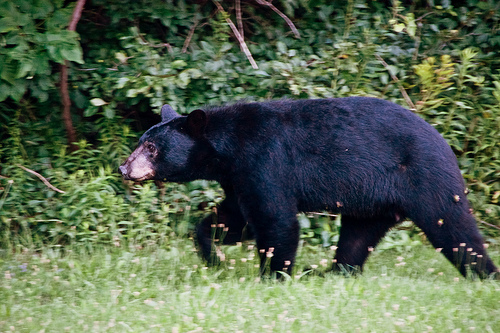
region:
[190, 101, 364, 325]
A black bear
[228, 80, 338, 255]
A black bear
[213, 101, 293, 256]
A black bear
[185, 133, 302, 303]
A black bear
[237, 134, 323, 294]
A black bear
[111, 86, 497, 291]
bear walking in the grass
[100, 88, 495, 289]
fuzzy black bear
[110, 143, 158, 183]
lighter colored snout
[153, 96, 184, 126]
rounded top, black ear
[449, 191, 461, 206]
light piece of nature sticking to the bear's fur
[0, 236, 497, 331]
patch of light green grass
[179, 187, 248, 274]
front leg is bent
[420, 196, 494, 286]
back leg is extended back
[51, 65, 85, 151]
skinny brown tree trunk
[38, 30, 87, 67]
large green leaf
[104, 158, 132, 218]
Bear has black nose.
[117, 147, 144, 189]
Bear has brown face.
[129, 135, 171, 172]
Bear has brown eyes.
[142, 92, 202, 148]
Bear has black ears.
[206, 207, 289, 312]
Bear has black front legs.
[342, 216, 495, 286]
Bear has black back paws.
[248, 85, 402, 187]
Bear has black back fur.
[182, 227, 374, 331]
Bear is walking through grass.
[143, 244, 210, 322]
Grass is green near bear.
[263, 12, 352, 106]
Leaves are green on tree.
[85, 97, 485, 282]
the bear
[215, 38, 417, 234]
the bear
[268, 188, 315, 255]
the bear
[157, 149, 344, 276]
the bear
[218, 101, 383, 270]
the bear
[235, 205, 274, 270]
the bear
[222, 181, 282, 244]
the bear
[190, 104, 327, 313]
the bear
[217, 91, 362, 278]
A bear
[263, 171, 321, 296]
A bear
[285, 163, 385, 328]
A bear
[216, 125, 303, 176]
A bear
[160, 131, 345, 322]
A bear